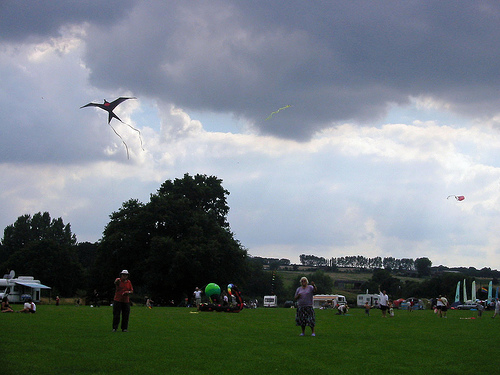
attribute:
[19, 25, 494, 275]
sky — dark